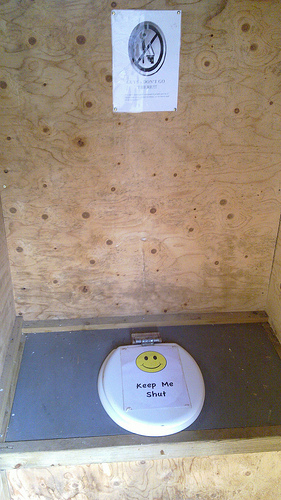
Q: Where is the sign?
A: On the toilet.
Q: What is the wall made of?
A: Wood.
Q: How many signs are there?
A: Two.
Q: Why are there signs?
A: To direct people.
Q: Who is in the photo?
A: Nobody.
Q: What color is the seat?
A: White.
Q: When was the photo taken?
A: Daytime.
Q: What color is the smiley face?
A: Yellow.